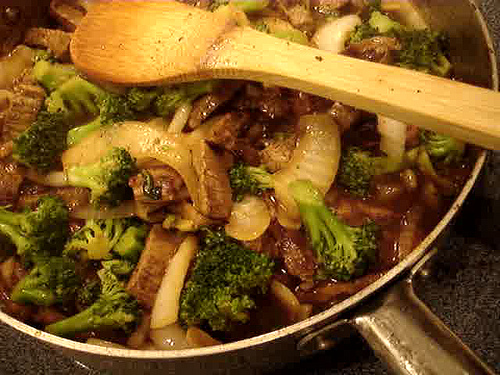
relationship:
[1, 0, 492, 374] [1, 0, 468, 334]
pot has vegetables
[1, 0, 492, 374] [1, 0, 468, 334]
pot with vegetables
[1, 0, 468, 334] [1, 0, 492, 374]
vegetables are in pot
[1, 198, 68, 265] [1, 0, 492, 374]
broccoli in pot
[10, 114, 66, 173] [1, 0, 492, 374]
broccoli in pot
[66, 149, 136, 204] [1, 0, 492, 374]
broccoli in pot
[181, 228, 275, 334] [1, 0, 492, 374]
broccoli in pot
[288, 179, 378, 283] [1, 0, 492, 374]
broccoli in pot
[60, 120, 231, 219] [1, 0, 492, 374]
onion in pot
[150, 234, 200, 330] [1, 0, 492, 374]
onion in pot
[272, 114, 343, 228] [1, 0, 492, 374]
onion in pot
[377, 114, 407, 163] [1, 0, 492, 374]
onion in pot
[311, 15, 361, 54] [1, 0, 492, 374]
onion in pot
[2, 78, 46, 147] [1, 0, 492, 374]
meat in pot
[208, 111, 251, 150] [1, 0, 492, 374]
meat in pot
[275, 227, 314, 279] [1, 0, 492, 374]
meat in pot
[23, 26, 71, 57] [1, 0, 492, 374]
meat in pot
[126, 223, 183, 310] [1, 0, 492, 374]
meat in pot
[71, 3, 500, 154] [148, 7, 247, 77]
spoon has speckles of food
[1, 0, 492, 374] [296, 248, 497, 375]
pot has handle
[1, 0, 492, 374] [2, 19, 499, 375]
pot on countertop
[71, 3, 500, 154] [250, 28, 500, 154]
spoon has handle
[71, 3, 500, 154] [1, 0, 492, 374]
spoon on top of pot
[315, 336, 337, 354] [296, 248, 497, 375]
screw holding handle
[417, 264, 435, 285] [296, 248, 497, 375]
screw holding handle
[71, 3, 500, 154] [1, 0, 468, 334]
spoon stirring vegetables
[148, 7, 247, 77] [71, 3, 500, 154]
speckles of food are on spoon